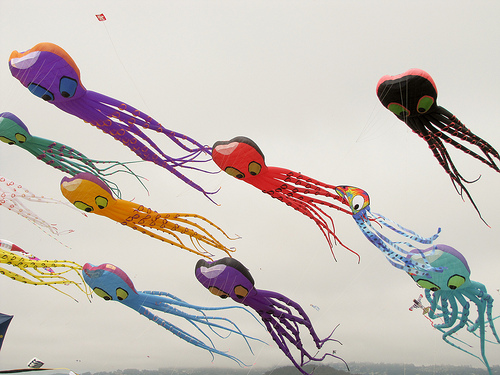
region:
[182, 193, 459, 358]
paintings of the octopuses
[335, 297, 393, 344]
the paper is white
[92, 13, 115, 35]
mark on the paper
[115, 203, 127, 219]
the octopus is orange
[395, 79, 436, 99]
the octopus is black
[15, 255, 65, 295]
legs of the octopus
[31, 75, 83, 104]
eyes of the octopus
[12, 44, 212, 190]
purple octopus kite at top left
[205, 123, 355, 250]
orange octopus kite in middle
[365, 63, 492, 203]
black octopus kite with green eyes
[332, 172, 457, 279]
tie-dye kite behind orange one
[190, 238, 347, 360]
purple kite with orange eyes at bottom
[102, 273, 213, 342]
blue octopus with green eyes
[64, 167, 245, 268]
yellow-orange octopus with green eyes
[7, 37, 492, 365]
group of multicolored octopus kites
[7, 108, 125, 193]
green octopus kite on left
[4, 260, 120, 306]
tentacles of a yellow octopus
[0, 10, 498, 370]
several octopus kites flying.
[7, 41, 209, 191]
purple and orange octopus kite in sky.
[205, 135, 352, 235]
red and black octopus kite in sky.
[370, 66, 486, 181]
black octopus kite flying.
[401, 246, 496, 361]
turquoise octopus kite in the air.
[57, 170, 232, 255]
orange octopus kite flying.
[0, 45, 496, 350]
eleven octopus kites flying in the air.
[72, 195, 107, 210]
yellow eyes on the octopus kite.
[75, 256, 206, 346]
blue and pink octopus kite.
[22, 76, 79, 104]
blue eyes on octopus kite.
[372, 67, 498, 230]
black and red octopus kite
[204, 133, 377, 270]
red and black octopus kite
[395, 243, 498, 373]
blue and purple octopus kite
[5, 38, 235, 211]
orange blue and purple octopus kite flying in the air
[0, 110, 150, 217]
green purple and yellow octopus kite flying near other octopus kites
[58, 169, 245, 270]
yellow and purple octopus kite flying in the air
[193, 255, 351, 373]
purple and black octopus kite flying near yellow octopus kite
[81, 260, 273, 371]
light blue and light purple octopus kite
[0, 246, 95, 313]
yellow tentacles of octopus kite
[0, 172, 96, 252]
pink red and white tentacles of octopus kite